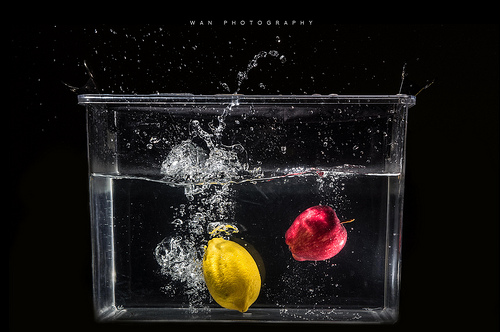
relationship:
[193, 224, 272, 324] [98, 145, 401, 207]
lemon in water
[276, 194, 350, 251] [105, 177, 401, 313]
apple in water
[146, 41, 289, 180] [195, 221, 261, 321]
water splash with lemon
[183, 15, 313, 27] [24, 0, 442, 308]
name of photo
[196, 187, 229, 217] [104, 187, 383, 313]
bubbles in water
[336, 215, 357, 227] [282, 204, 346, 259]
stem of apple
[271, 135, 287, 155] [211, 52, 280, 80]
spots of water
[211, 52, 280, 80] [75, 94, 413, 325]
water on bowl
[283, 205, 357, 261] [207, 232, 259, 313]
apple and lemon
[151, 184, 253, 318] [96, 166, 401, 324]
bubbles in water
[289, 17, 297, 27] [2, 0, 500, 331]
white letter on photo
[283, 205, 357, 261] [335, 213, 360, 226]
apple has stem